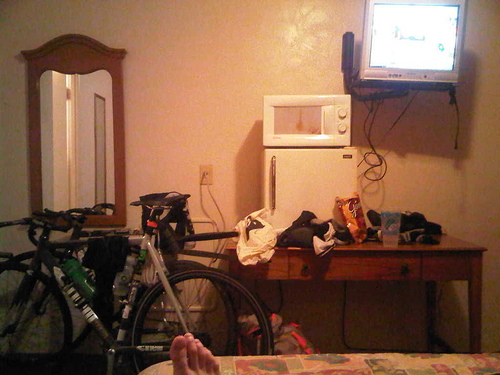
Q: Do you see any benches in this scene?
A: No, there are no benches.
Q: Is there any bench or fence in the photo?
A: No, there are no benches or fences.